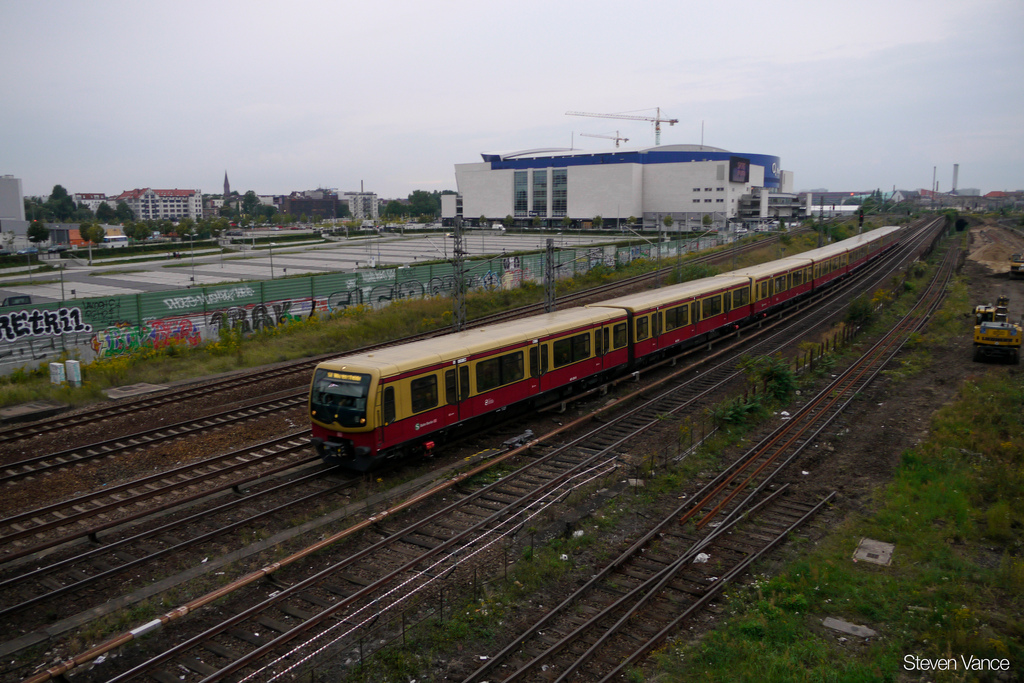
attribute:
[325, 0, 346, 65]
cloud — white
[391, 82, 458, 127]
cloud — white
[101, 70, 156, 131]
cloud — white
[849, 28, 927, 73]
cloud — white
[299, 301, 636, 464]
train — long, yellow, red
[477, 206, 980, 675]
tracks — empty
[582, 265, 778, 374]
train — green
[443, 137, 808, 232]
building — large, white, commercial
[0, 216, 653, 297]
parking lot — large, empty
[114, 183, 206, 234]
building — large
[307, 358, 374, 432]
window — large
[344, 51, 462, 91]
clouds — white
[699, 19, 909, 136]
sky — blue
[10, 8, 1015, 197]
sky — blue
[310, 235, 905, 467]
bottom — red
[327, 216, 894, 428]
top — yellow